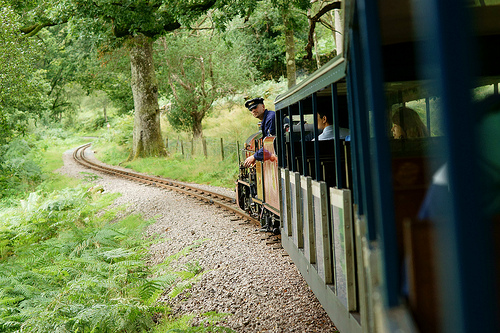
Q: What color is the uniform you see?
A: Blue.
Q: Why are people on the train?
A: To ride.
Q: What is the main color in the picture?
A: Green.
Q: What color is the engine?
A: Red.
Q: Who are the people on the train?
A: Passengers.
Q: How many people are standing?
A: One.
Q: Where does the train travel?
A: On the tracks.